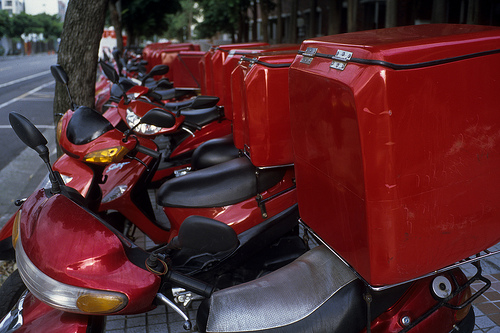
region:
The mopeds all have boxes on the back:
[0, 26, 499, 331]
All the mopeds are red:
[0, 24, 499, 328]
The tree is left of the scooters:
[52, 0, 109, 155]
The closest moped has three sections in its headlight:
[0, 203, 130, 323]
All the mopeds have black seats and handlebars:
[7, 51, 419, 331]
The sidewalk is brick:
[98, 241, 498, 329]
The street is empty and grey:
[3, 49, 109, 216]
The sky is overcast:
[24, 1, 61, 20]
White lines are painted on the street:
[0, 67, 55, 133]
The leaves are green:
[0, 0, 273, 40]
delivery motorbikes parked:
[0, 6, 496, 332]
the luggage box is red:
[291, 28, 498, 288]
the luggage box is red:
[246, 63, 288, 164]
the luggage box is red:
[203, 47, 230, 135]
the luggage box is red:
[167, 51, 199, 86]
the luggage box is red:
[140, 39, 159, 63]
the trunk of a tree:
[52, 0, 101, 114]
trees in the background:
[0, 1, 60, 58]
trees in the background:
[112, 0, 499, 37]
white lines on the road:
[0, 68, 64, 135]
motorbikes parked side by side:
[25, 15, 471, 318]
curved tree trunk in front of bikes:
[35, 0, 130, 130]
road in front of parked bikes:
[5, 7, 50, 153]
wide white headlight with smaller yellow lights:
[5, 210, 125, 320]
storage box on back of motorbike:
[275, 5, 492, 290]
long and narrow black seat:
[152, 135, 267, 215]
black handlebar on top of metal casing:
[2, 72, 243, 297]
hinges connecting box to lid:
[287, 31, 362, 81]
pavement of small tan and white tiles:
[100, 255, 495, 327]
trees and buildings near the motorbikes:
[106, 3, 491, 41]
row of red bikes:
[13, 43, 290, 295]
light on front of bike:
[8, 230, 113, 315]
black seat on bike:
[169, 152, 262, 198]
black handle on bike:
[163, 216, 258, 315]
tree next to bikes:
[43, 8, 113, 98]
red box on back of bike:
[270, 40, 495, 272]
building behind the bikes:
[250, 7, 353, 34]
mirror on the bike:
[178, 208, 228, 264]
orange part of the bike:
[77, 137, 126, 175]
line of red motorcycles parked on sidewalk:
[2, 38, 486, 331]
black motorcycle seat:
[153, 155, 262, 211]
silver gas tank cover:
[428, 276, 455, 300]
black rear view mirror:
[4, 110, 69, 190]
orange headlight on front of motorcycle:
[68, 284, 123, 316]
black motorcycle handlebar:
[133, 143, 164, 160]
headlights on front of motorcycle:
[7, 216, 127, 322]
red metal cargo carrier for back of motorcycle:
[286, 21, 499, 282]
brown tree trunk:
[51, 1, 110, 127]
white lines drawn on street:
[3, 73, 51, 106]